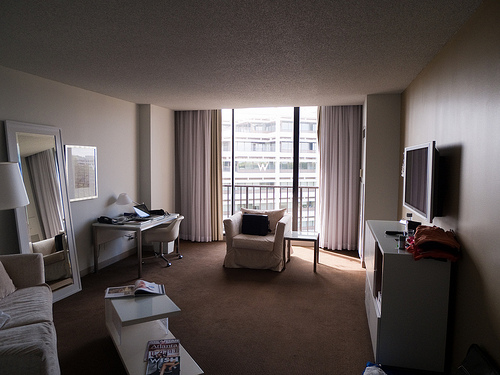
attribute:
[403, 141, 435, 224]
tv — flat, mounted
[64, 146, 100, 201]
picture — framed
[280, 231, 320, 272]
table — wooden, full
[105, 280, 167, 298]
magazine — open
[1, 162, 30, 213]
lamp — white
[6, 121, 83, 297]
mirror — white, leaning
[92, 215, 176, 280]
table — full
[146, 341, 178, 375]
magazine — white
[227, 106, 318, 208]
door — sliding